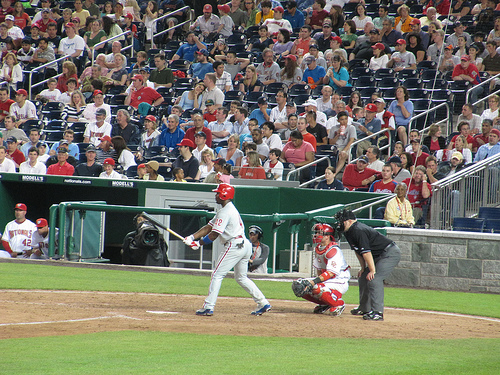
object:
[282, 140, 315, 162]
shirt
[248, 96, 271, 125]
man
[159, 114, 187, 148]
man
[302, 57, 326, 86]
man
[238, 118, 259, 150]
man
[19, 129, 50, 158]
man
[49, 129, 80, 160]
man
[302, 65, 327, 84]
blue shirt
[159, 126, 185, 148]
blue shirt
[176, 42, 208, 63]
blue shirt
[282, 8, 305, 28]
blue shirt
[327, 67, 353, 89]
blue shirt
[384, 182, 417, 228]
man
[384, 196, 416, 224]
shirt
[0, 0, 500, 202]
crowd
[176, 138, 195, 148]
hat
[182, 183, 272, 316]
batter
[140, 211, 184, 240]
bat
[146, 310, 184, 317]
plate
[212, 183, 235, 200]
helmet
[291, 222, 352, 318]
catcher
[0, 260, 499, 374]
ground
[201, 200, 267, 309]
uniform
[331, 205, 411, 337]
umpire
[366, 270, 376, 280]
hand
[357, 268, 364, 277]
hand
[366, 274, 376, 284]
knee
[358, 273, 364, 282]
knee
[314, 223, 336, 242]
helmet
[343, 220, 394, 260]
shirt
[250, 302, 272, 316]
shoe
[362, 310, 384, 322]
shoe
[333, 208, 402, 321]
pants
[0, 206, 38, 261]
player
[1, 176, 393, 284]
dugout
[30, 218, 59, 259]
player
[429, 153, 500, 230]
railing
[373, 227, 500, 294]
wall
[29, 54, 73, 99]
railing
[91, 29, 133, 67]
railing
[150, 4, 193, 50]
railing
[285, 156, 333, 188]
railing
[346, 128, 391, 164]
railing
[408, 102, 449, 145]
railing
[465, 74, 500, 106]
railing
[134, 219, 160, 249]
camera